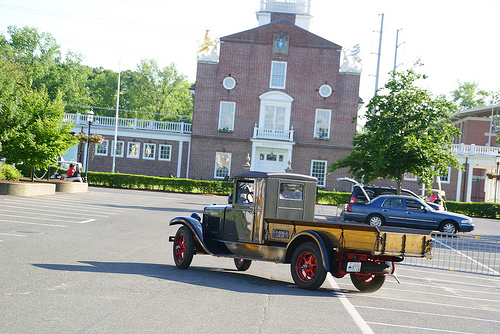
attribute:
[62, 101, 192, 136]
railing — white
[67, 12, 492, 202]
building — brick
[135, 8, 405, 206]
brick building — bricked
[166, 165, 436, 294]
truck — antique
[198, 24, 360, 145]
wall — white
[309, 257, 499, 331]
white lines — painted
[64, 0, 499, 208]
brick buildnig — red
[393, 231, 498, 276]
railing — metal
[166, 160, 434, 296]
car — old timey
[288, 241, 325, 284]
tire — rear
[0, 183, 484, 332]
lot — parking